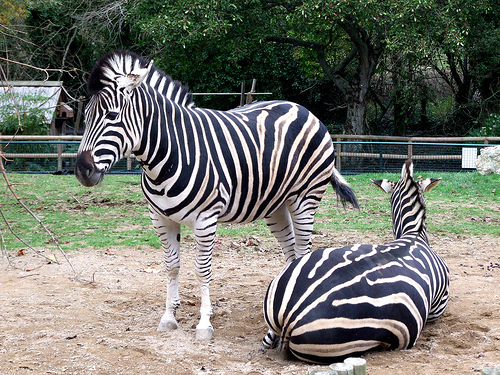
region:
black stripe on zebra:
[311, 301, 359, 325]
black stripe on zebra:
[344, 286, 389, 296]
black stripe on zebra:
[371, 263, 409, 288]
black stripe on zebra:
[404, 263, 441, 318]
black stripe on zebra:
[324, 268, 370, 289]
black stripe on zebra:
[356, 246, 376, 263]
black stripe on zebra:
[401, 217, 421, 230]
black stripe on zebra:
[399, 192, 426, 219]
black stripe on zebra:
[392, 181, 413, 201]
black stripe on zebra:
[275, 115, 302, 174]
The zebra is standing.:
[72, 45, 360, 345]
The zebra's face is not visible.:
[255, 155, 455, 352]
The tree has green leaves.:
[115, 0, 470, 167]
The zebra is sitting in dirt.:
[255, 155, 450, 365]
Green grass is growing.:
[55, 190, 142, 235]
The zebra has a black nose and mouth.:
[70, 150, 100, 185]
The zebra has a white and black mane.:
[75, 45, 196, 110]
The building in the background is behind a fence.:
[0, 76, 71, 171]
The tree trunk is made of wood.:
[342, 82, 362, 172]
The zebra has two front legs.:
[150, 209, 218, 341]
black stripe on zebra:
[156, 150, 186, 184]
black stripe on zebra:
[211, 131, 242, 166]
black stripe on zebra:
[234, 120, 269, 147]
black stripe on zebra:
[279, 116, 317, 149]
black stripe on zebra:
[258, 173, 293, 188]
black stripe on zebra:
[216, 158, 272, 200]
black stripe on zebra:
[189, 178, 229, 219]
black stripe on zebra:
[194, 218, 221, 243]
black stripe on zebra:
[193, 244, 216, 271]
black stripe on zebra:
[136, 136, 198, 196]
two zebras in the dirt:
[63, 40, 455, 366]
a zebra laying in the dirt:
[261, 161, 468, 366]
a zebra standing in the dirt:
[65, 39, 352, 351]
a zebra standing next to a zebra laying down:
[67, 45, 454, 373]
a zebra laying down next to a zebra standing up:
[64, 41, 459, 367]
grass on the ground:
[5, 170, 149, 250]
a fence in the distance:
[338, 127, 498, 189]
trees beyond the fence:
[169, 7, 498, 169]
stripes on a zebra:
[305, 264, 405, 340]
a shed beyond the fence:
[1, 70, 80, 148]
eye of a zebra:
[104, 110, 121, 121]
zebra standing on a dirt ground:
[72, 48, 362, 341]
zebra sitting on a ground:
[260, 158, 452, 366]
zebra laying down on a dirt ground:
[261, 157, 451, 365]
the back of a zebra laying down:
[263, 158, 453, 363]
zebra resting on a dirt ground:
[260, 155, 452, 367]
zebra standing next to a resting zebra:
[68, 47, 453, 366]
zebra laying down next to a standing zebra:
[71, 46, 451, 365]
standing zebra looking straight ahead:
[72, 45, 363, 340]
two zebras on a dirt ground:
[73, 45, 453, 364]